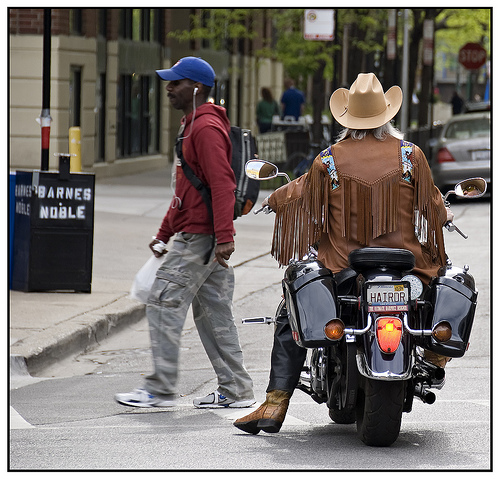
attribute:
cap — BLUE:
[154, 51, 223, 101]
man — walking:
[154, 77, 242, 261]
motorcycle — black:
[275, 243, 476, 438]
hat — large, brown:
[328, 69, 407, 131]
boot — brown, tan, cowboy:
[234, 387, 300, 431]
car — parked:
[428, 111, 490, 182]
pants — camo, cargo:
[156, 227, 248, 392]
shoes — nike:
[195, 385, 249, 407]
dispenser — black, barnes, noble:
[15, 161, 103, 292]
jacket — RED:
[144, 110, 242, 264]